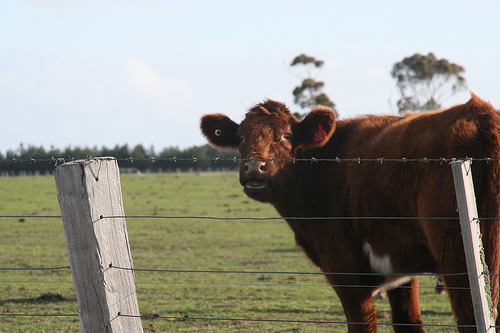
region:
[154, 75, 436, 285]
furry brown cow mooing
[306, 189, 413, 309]
white patch of fur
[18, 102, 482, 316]
barbed wire with wooden fence posts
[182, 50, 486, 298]
furry brown cow in a field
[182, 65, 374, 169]
large ears sticking out from cows head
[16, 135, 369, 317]
large green field for cows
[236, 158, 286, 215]
open mouth of a cow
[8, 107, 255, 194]
line of green trees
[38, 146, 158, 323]
thick wooden fence post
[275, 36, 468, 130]
tall trees with leafy tops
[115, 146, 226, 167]
Top of silver wire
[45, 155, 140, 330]
Grey wood inbetween wire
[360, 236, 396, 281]
White patch in cows fur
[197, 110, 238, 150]
Left ear of cow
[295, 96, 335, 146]
Right ear of cow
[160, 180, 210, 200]
Green grass in field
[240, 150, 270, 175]
Brown nose on cow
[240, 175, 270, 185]
Brown lips on cow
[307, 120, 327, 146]
Pinkish tag in cow ear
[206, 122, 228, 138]
Black and white button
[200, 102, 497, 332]
a fluffy long haired brown cow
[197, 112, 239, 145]
the ear of a cow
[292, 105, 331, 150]
the ear of a cow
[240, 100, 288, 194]
the head of a cow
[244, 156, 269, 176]
the nose of a cow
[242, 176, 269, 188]
the mouth of a cow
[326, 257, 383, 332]
the leg of a cow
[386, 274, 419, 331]
the leg of a cow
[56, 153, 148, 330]
a wooden fence post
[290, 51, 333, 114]
a tall tree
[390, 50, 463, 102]
large trees with green leaves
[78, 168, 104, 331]
grey wooden fence post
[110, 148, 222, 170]
metal barb wire at top of fence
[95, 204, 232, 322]
small metal wire fencing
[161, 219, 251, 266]
green grass growing in field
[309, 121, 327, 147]
red tag in ear of cow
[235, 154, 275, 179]
brown nose of cow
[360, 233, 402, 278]
white spot on side of car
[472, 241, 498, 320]
moss growing on side of fence post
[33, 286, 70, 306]
pile of animal droppings in field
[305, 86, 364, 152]
ear of the animal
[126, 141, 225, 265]
fence next to the animal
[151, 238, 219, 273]
green grass on the ground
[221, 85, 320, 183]
head of the animal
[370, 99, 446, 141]
back of the animal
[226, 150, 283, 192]
nose of the animal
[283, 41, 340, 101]
tree behind the animal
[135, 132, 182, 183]
trees next to grass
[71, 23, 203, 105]
blue sky above the tree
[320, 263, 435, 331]
legs of the animal